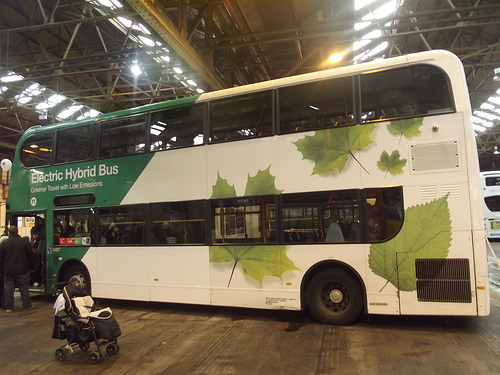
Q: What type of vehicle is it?
A: A bus.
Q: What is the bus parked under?
A: A metal structure.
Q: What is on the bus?
A: Windows.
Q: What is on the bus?
A: Decals.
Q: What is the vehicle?
A: A bus.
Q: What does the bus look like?
A: White and green.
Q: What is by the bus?
A: A stroller.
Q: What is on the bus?
A: Leaves.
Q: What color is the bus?
A: Green and white.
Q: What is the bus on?
A: Cement.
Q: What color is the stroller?
A: Black and white.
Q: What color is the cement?
A: Gray.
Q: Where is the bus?
A: On the cement.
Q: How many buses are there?
A: One.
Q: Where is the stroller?
A: Next to the bus.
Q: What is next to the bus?
A: The stroller.